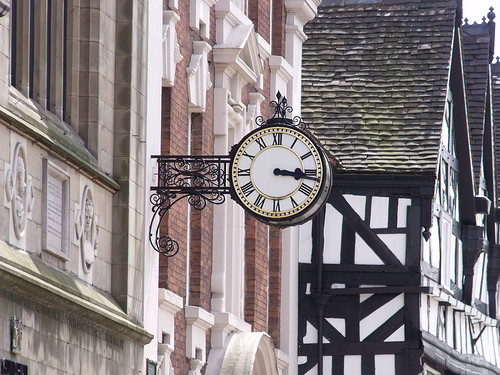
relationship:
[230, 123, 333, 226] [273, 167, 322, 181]
clock has hands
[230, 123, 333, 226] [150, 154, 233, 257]
clock on a post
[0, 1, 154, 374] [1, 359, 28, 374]
building has black tiles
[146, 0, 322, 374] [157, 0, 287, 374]
building has red brick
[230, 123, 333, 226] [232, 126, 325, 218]
clock has a gold border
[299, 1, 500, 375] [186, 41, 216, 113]
building has details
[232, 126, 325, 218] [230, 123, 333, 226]
gold border on clock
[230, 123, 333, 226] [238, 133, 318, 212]
clock has roman numbers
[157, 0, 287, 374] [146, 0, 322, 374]
red brick part of building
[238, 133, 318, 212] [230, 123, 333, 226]
roman numbers are on clock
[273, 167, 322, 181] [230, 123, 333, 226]
hands are for clock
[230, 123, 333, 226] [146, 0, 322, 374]
clock on building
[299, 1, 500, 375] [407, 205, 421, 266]
building covered with wood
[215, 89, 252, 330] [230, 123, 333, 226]
window behind clock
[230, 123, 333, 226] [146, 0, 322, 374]
clock connected to building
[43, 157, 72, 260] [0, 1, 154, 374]
plaque on building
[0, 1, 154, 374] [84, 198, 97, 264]
building has a face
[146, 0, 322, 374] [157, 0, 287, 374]
building made of red brick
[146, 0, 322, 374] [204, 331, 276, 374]
building has an archway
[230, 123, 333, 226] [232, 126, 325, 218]
clock has a face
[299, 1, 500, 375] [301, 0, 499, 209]
building has a roof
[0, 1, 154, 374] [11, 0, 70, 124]
building has windows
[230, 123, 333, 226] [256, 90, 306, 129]
clock has decorations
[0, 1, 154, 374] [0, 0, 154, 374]
building has cement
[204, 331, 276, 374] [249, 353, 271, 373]
archway of doorway